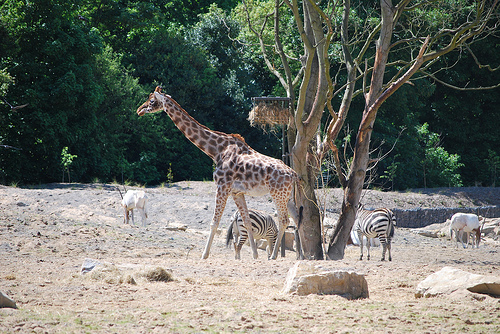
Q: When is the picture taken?
A: Daytime.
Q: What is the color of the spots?
A: Brown.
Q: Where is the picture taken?
A: At a wildlife park.